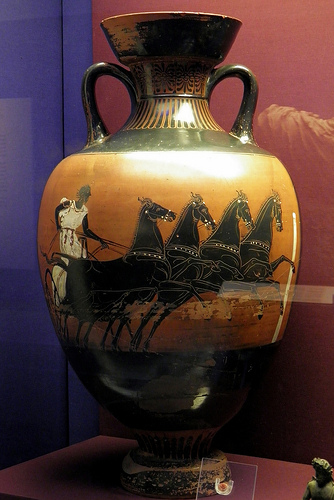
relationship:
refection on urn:
[187, 379, 214, 414] [34, 10, 318, 497]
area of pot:
[209, 460, 239, 489] [36, 10, 303, 496]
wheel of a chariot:
[43, 269, 63, 334] [41, 248, 124, 342]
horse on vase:
[256, 189, 288, 270] [26, 6, 310, 496]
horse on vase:
[197, 187, 274, 325] [26, 6, 310, 496]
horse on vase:
[176, 189, 216, 291] [26, 6, 310, 496]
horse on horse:
[126, 195, 175, 286] [256, 189, 288, 270]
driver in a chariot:
[50, 184, 110, 309] [43, 251, 128, 349]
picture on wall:
[256, 103, 333, 176] [2, 0, 332, 491]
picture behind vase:
[256, 103, 333, 176] [26, 6, 310, 496]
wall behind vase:
[2, 0, 332, 491] [26, 6, 310, 496]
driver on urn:
[54, 184, 96, 260] [34, 10, 318, 497]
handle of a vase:
[204, 63, 261, 147] [26, 6, 310, 496]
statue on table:
[302, 455, 333, 497] [2, 436, 330, 497]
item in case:
[214, 477, 234, 495] [194, 456, 256, 498]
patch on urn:
[97, 346, 243, 406] [34, 10, 318, 497]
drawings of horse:
[52, 163, 284, 334] [241, 189, 294, 318]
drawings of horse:
[52, 163, 284, 334] [198, 189, 271, 296]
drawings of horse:
[52, 163, 284, 334] [130, 191, 215, 352]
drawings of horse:
[52, 163, 284, 334] [40, 195, 175, 351]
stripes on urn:
[101, 236, 179, 282] [34, 10, 318, 497]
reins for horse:
[96, 229, 131, 253] [237, 190, 298, 323]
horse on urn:
[237, 190, 298, 323] [34, 10, 318, 497]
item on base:
[213, 477, 234, 497] [120, 446, 234, 500]